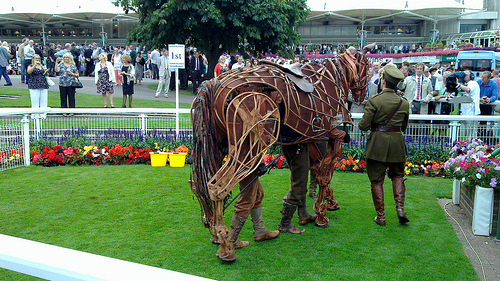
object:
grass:
[5, 164, 187, 238]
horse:
[187, 46, 368, 263]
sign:
[165, 43, 187, 69]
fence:
[34, 108, 498, 152]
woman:
[26, 54, 55, 118]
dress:
[95, 62, 116, 93]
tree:
[115, 1, 310, 95]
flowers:
[79, 146, 93, 155]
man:
[397, 62, 434, 116]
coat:
[397, 75, 433, 114]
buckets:
[150, 152, 168, 168]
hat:
[383, 65, 405, 85]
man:
[276, 125, 318, 236]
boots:
[277, 197, 307, 234]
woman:
[93, 52, 117, 107]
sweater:
[93, 61, 116, 84]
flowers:
[31, 154, 43, 163]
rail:
[2, 106, 190, 118]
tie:
[416, 76, 421, 101]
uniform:
[357, 65, 410, 227]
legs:
[278, 132, 305, 235]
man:
[456, 69, 482, 143]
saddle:
[257, 58, 316, 93]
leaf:
[256, 34, 261, 40]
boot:
[370, 182, 386, 225]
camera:
[444, 76, 458, 96]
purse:
[70, 76, 83, 88]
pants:
[29, 87, 49, 120]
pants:
[59, 84, 77, 109]